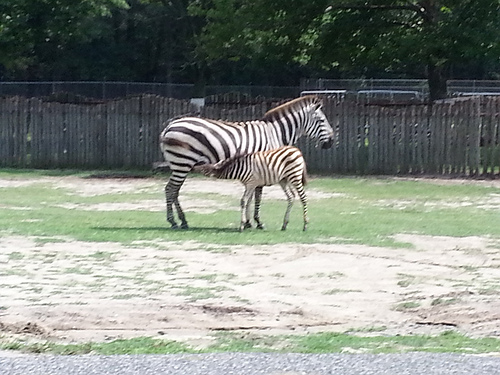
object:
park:
[0, 0, 500, 375]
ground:
[351, 245, 462, 303]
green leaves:
[186, 5, 498, 67]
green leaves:
[62, 0, 95, 38]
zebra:
[151, 95, 335, 230]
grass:
[60, 216, 120, 235]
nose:
[329, 133, 334, 147]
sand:
[158, 245, 484, 327]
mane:
[262, 95, 324, 121]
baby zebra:
[190, 145, 310, 232]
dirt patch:
[132, 250, 422, 318]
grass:
[219, 331, 494, 353]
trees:
[0, 0, 500, 98]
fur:
[160, 125, 276, 158]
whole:
[350, 119, 375, 170]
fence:
[0, 90, 499, 179]